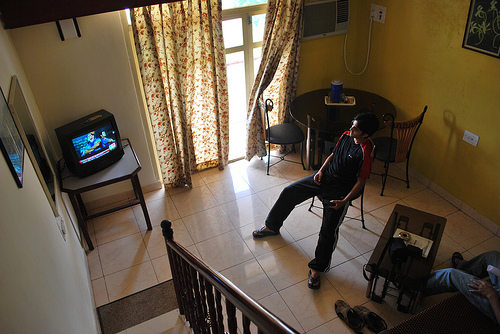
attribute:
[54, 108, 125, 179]
television — on, old style, box, black, small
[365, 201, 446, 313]
coffee table — glass, black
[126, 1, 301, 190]
curtains — open, floral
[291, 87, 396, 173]
table — round, glass, black, small, circular, in corner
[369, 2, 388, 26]
electrical outlet — white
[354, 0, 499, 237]
wall — yellow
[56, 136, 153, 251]
table — small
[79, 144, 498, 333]
floor — tiled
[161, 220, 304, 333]
banaster — wood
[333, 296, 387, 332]
shoes — slip on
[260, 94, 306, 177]
chair — metal, black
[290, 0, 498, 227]
walls — mustard yellow